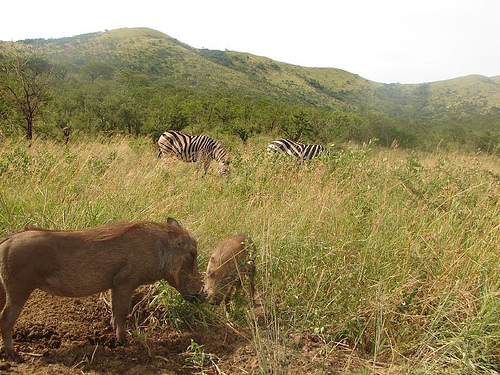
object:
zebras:
[154, 129, 230, 177]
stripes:
[158, 132, 183, 161]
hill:
[0, 26, 500, 153]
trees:
[1, 47, 56, 141]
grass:
[0, 133, 498, 374]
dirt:
[0, 296, 363, 374]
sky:
[0, 1, 500, 85]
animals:
[1, 218, 206, 359]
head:
[217, 147, 232, 175]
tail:
[154, 132, 163, 157]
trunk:
[25, 108, 34, 144]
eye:
[185, 253, 195, 269]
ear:
[165, 215, 184, 244]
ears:
[226, 145, 233, 158]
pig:
[204, 235, 251, 305]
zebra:
[151, 128, 236, 178]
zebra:
[264, 137, 335, 163]